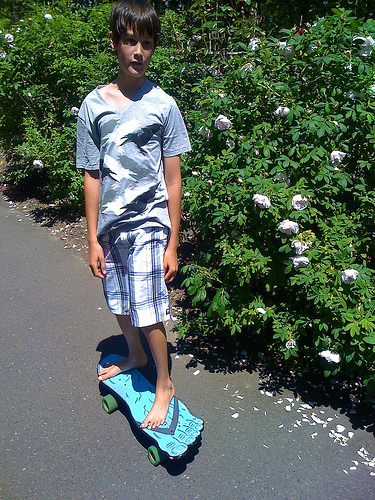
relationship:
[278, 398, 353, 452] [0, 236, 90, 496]
petals are on ground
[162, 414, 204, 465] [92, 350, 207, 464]
toes on a fake foot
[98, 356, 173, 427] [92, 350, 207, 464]
feet on top of skateboard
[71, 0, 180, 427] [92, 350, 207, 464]
boy riding skateboard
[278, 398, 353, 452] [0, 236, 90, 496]
petals on road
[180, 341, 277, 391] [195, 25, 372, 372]
shadow from bushes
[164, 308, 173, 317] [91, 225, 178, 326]
logo on shorts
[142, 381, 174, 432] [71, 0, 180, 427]
feet of boy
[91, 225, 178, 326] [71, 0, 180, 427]
shorts on boy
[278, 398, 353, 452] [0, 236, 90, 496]
petals on path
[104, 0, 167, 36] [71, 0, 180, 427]
hair of boy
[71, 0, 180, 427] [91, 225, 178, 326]
boy wearing shorts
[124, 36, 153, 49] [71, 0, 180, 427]
eyes of boy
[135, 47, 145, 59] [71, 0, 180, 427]
nose of boy